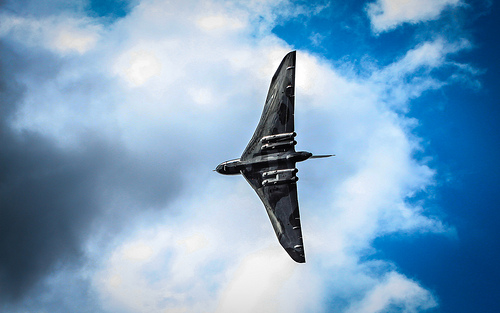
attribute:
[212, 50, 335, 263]
jet — black, gray, soaring, grey, flying, futuristic, dark grey, military, sideways, moving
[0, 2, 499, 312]
sky — blue, cloudy, clear, bright blue, dark blue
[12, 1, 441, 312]
cloud — white, huge, puffy, cumulous, thick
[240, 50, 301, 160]
wing — black, triangle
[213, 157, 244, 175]
nose — small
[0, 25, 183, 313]
cloud — black, stormy, dark